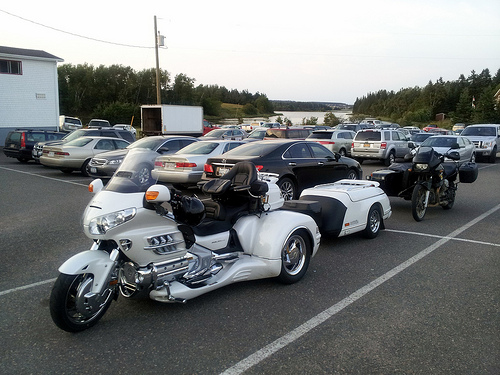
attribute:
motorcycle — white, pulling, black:
[52, 176, 322, 292]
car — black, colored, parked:
[258, 136, 327, 185]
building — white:
[1, 43, 73, 132]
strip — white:
[330, 282, 374, 306]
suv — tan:
[357, 124, 399, 161]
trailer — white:
[306, 180, 408, 239]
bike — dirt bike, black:
[400, 169, 452, 230]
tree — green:
[77, 59, 123, 105]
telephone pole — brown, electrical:
[143, 47, 170, 61]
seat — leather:
[203, 165, 253, 208]